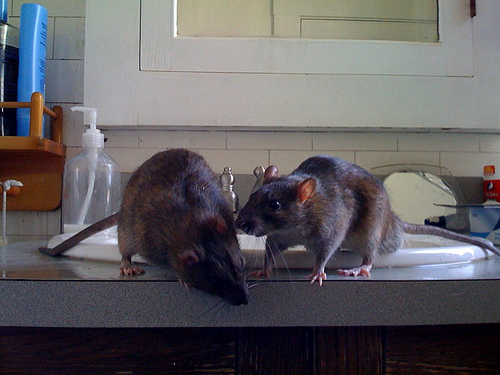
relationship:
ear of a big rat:
[295, 175, 317, 207] [233, 153, 499, 287]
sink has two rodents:
[414, 230, 469, 263] [119, 145, 400, 283]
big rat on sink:
[233, 153, 499, 287] [73, 207, 497, 295]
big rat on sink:
[233, 153, 499, 287] [59, 213, 472, 255]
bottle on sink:
[59, 106, 122, 234] [67, 218, 476, 289]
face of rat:
[233, 177, 296, 238] [234, 153, 397, 284]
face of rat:
[233, 177, 299, 239] [35, 150, 246, 307]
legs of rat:
[254, 240, 376, 286] [231, 155, 484, 285]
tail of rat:
[35, 211, 119, 259] [35, 150, 246, 307]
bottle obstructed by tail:
[59, 107, 116, 228] [37, 216, 124, 259]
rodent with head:
[34, 150, 252, 306] [174, 234, 261, 316]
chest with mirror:
[86, 10, 484, 120] [182, 2, 442, 40]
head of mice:
[236, 156, 317, 238] [241, 150, 482, 289]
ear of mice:
[233, 156, 482, 292] [261, 160, 280, 179]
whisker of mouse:
[266, 232, 300, 296] [235, 162, 402, 274]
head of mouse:
[231, 163, 317, 237] [118, 146, 253, 309]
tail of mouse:
[35, 211, 119, 259] [45, 147, 255, 307]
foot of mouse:
[120, 256, 136, 275] [48, 138, 242, 307]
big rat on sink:
[233, 153, 499, 287] [62, 218, 482, 275]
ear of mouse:
[295, 175, 317, 207] [233, 151, 483, 282]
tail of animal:
[402, 220, 484, 253] [237, 154, 483, 279]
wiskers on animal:
[257, 229, 297, 307] [234, 156, 481, 290]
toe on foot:
[308, 273, 318, 286] [300, 267, 329, 287]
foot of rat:
[300, 267, 329, 287] [231, 155, 484, 285]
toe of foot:
[317, 274, 323, 287] [300, 267, 329, 287]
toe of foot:
[340, 264, 346, 274] [340, 260, 374, 276]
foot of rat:
[340, 260, 374, 276] [234, 157, 484, 275]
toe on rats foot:
[308, 273, 318, 286] [309, 216, 351, 302]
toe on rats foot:
[308, 273, 318, 286] [292, 205, 345, 305]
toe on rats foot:
[308, 273, 318, 286] [305, 196, 356, 289]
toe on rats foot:
[308, 273, 318, 286] [242, 210, 305, 291]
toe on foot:
[123, 254, 142, 286] [114, 261, 148, 277]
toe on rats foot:
[131, 268, 141, 276] [86, 200, 151, 292]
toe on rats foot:
[112, 256, 132, 278] [109, 210, 152, 285]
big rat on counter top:
[233, 153, 499, 287] [7, 182, 497, 337]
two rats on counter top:
[110, 131, 398, 299] [14, 221, 498, 337]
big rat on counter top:
[233, 153, 499, 287] [14, 221, 498, 337]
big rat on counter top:
[233, 153, 499, 287] [22, 218, 496, 346]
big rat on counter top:
[233, 153, 499, 287] [9, 207, 490, 349]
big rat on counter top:
[233, 153, 499, 287] [30, 201, 480, 343]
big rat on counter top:
[253, 139, 438, 275] [9, 196, 488, 355]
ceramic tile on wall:
[477, 132, 499, 153] [28, 109, 494, 202]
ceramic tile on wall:
[477, 132, 499, 153] [47, 96, 498, 205]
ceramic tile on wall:
[399, 125, 489, 155] [47, 96, 498, 205]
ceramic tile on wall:
[477, 132, 499, 153] [49, 117, 487, 216]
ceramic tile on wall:
[477, 132, 499, 153] [50, 120, 487, 232]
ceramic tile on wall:
[199, 140, 271, 180] [61, 120, 496, 196]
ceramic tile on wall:
[477, 132, 499, 153] [74, 120, 483, 215]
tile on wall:
[104, 142, 172, 172] [2, 2, 499, 239]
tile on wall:
[268, 150, 354, 175] [2, 2, 499, 239]